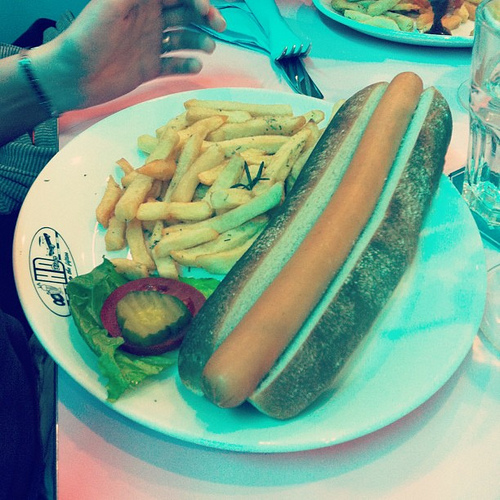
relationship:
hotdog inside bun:
[195, 67, 431, 414] [169, 67, 453, 424]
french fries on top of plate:
[90, 96, 344, 280] [10, 87, 489, 456]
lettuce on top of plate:
[64, 254, 222, 403] [10, 87, 489, 456]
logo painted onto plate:
[27, 223, 77, 317] [10, 87, 489, 456]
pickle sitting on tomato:
[112, 285, 191, 349] [88, 274, 211, 356]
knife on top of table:
[274, 54, 326, 101] [46, 2, 499, 499]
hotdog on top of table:
[195, 67, 431, 414] [46, 2, 499, 499]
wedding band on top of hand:
[160, 33, 172, 56] [61, 0, 229, 106]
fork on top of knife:
[239, 0, 315, 66] [274, 54, 326, 101]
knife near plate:
[274, 54, 326, 101] [10, 87, 489, 456]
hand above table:
[61, 0, 229, 106] [46, 2, 499, 499]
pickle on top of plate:
[112, 285, 191, 349] [10, 87, 489, 456]